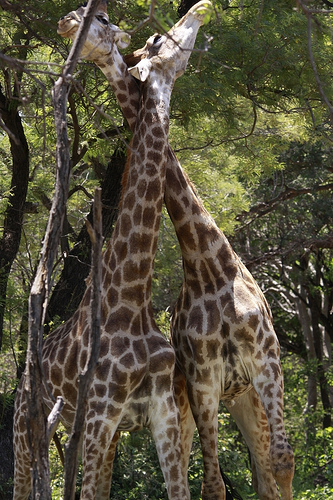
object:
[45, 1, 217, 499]
giraffe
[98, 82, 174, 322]
neck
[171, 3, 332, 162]
tree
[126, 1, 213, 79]
head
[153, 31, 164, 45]
eye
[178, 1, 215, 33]
mouth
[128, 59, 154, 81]
ear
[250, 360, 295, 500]
leg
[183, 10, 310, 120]
leaves